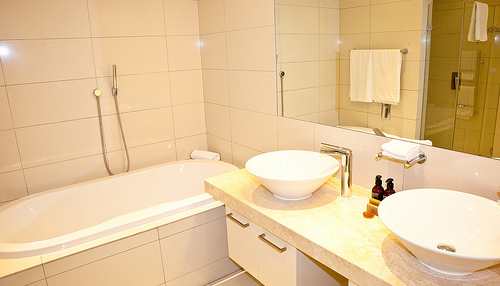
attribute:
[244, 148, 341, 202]
sink — white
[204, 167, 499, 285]
counter — marble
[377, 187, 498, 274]
sink — white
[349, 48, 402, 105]
towel — white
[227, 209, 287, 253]
handles — steel, metal, silver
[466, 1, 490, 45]
towel — white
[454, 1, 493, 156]
door — glass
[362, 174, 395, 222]
toiletries — small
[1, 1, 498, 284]
room — clean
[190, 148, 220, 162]
towel — small, white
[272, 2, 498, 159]
mirror — reflecting, large, frameless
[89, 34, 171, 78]
tile — white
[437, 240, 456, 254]
drain — metal, silver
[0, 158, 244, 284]
tub — empty, white, large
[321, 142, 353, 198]
faucet — metal, silver